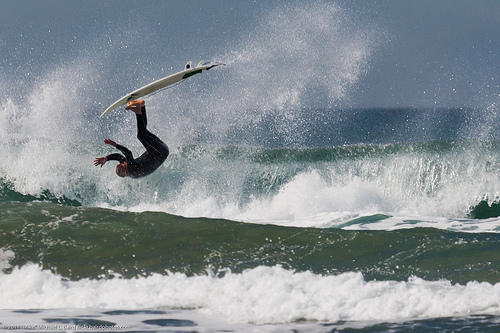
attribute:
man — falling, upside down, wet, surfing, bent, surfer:
[97, 101, 171, 178]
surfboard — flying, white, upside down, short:
[99, 61, 227, 119]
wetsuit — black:
[105, 116, 167, 176]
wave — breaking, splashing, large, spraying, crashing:
[2, 130, 498, 225]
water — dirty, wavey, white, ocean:
[12, 109, 499, 333]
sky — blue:
[2, 6, 499, 117]